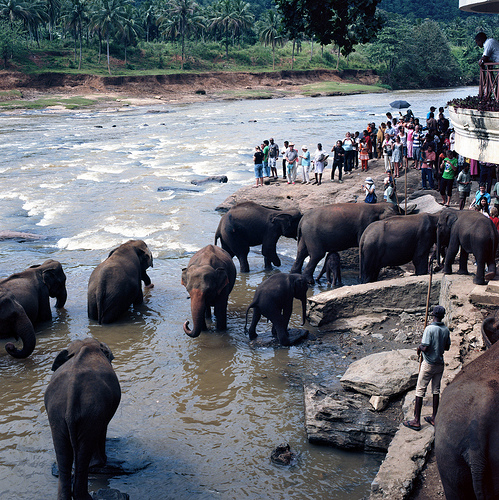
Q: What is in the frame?
A: The back end of the elephant.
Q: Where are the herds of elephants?
A: In the water.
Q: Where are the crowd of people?
A: By the water.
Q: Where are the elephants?
A: In a river with medium flow rapids.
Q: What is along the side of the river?
A: Large boulders.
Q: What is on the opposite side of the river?
A: Dirt cliffs.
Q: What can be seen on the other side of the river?
A: A jungle.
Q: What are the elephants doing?
A: Bathing in the river.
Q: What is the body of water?
A: A river.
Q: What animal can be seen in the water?
A: Elephants.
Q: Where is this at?
A: River.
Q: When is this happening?
A: During the day time.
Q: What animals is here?
A: Elephants.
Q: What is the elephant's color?
A: Gray.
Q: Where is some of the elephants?
A: In water.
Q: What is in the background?
A: Trees.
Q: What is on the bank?
A: Some people.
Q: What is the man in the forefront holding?
A: Brown stick.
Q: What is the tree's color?
A: Green.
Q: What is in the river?
A: Elephants.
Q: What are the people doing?
A: Watching the elephants.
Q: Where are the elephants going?
A: They are leaving the water.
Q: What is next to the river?
A: A rock wall.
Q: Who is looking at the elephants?
A: A crowd of people.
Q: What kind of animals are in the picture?
A: Elephants.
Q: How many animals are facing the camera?
A: One.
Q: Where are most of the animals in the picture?
A: In a river.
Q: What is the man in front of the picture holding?
A: A stick.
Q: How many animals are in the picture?
A: Eleven.